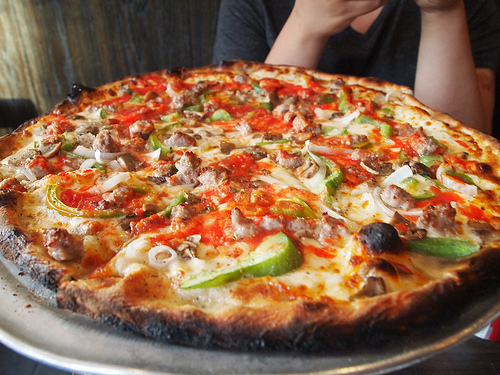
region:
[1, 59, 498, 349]
a multi topping pizza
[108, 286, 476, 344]
burnt crust on the pizza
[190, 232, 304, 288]
green pepper on the pizza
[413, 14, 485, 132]
left forearm of person sitting near pizza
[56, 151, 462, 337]
a slice of pizza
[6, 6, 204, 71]
fence behind pizza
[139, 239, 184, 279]
onion on the pizza topping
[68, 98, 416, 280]
many pizza toppings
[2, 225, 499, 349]
burned pizza crust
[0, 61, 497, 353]
a baked burned pizza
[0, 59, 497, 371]
pizza on a round pan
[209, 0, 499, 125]
a person wearing a black shirt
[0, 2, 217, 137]
a brown wooden wall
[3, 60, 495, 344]
a baked pizza supreme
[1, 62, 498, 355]
a cut pizza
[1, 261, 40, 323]
crumbs on the pan from cutting the crust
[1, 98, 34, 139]
a dark shadow on the wall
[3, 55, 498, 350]
this is pizza in a plate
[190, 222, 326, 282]
this is a topping on the pizza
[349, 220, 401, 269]
this is a topping on the pizza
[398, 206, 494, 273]
this is a topping on the pizza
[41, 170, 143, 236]
this is a topping on the pizza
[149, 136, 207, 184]
this is a topping on the pizza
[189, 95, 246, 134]
this is a topping on the pizza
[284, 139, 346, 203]
this is a topping on the pizza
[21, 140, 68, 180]
this is a topping on the pizza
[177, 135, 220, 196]
this is a topping on the pizza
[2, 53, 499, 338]
a baked pizza pie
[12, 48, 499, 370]
pizza with a lot of toppings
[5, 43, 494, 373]
pizza on a round metal pan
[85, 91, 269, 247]
toppings on a pizza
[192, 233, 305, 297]
a slice of green pepper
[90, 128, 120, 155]
a piece of sausage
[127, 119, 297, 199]
cheese on a pizza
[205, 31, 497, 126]
a person sitting near a pizza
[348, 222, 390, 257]
A piece of food.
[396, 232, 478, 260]
A piece of food.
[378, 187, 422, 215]
A piece of food.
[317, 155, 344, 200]
A piece of food.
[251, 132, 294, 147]
A piece of food.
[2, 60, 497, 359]
pizza sits on tray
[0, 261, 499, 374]
tray underneath pizza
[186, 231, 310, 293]
pepper sits on pizza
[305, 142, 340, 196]
pepper sits on pizza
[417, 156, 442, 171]
pepper sits on pizza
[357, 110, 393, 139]
pepper sits on pizza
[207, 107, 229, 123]
pepper sits on pizza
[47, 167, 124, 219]
pepper sits on pizza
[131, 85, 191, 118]
red sauce and toppings on pizza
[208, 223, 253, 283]
red sauce and toppings on pizza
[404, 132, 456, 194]
red sauce and toppings on pizza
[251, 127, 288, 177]
red sauce and toppings on pizza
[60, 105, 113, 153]
red sauce and toppings on pizza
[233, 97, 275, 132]
red sauce and toppings on pizza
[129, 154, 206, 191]
red sauce and toppings on pizza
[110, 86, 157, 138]
red sauce and toppings on pizza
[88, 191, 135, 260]
red sauce and toppings on pizza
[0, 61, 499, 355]
large pizza on a metal platter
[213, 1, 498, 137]
a person sitting behind the pizza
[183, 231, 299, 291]
a slice of green pepper on the pizza